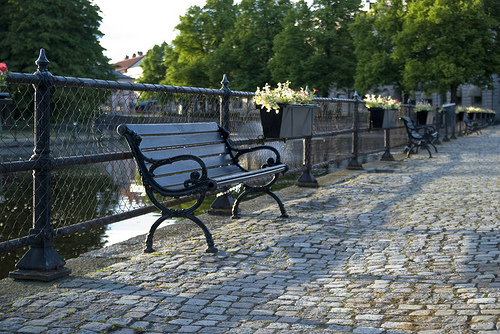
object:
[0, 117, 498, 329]
walkway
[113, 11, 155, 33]
sky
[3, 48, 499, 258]
fence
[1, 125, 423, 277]
pond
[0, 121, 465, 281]
pond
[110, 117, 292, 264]
bench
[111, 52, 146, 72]
roof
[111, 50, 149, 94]
building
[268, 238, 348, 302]
ground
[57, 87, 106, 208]
fence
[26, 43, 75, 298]
post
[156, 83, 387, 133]
fence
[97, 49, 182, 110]
house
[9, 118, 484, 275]
river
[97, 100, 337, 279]
bench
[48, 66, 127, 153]
fence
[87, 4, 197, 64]
sky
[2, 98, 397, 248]
pond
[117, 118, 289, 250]
bench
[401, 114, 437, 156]
bench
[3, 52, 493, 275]
fence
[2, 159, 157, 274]
river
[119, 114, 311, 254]
bench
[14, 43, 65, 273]
pole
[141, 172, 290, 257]
legs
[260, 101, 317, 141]
flower pot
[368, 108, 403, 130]
flower pot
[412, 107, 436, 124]
flower pot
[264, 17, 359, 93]
leaves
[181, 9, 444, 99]
trees.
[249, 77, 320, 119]
elephant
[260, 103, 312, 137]
container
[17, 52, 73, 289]
post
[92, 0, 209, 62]
sky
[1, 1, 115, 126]
tree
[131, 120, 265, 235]
bench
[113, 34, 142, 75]
building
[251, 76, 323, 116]
plant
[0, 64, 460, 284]
fence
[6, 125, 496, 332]
walkaway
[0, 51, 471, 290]
fence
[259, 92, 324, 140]
container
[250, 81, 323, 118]
plant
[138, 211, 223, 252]
leg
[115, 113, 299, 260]
bench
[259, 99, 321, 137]
planter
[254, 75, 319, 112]
flower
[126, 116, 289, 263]
bench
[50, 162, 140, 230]
pond